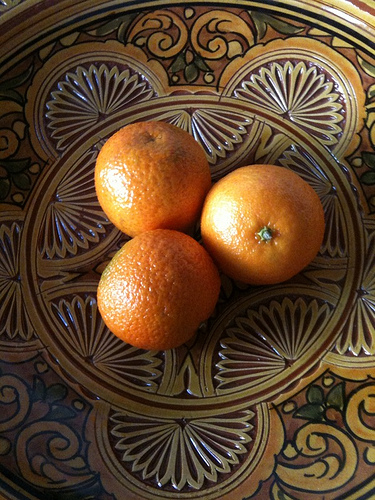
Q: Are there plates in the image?
A: Yes, there is a plate.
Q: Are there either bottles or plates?
A: Yes, there is a plate.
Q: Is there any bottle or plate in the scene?
A: Yes, there is a plate.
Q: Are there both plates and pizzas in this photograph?
A: No, there is a plate but no pizzas.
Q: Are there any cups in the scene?
A: No, there are no cups.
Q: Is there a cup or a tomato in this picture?
A: No, there are no cups or tomatoes.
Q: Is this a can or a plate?
A: This is a plate.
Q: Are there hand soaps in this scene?
A: No, there are no hand soaps.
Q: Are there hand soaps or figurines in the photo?
A: No, there are no hand soaps or figurines.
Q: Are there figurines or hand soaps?
A: No, there are no hand soaps or figurines.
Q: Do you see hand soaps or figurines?
A: No, there are no hand soaps or figurines.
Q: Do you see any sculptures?
A: No, there are no sculptures.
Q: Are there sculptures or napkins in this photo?
A: No, there are no sculptures or napkins.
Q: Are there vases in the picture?
A: No, there are no vases.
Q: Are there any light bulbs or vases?
A: No, there are no vases or light bulbs.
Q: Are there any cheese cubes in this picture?
A: No, there are no cheese cubes.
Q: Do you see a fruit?
A: Yes, there is a fruit.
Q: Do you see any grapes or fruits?
A: Yes, there is a fruit.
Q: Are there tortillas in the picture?
A: No, there are no tortillas.